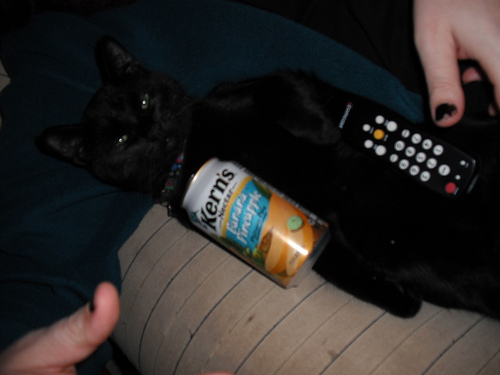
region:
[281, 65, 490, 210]
a cell phone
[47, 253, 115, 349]
a thumb with a black nail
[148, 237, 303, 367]
a striped pattern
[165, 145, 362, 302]
a can of something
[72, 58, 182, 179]
cats eyes in the dark area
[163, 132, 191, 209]
something of color under cat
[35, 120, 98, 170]
a cats ear in the darkness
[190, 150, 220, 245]
kerns is written on the can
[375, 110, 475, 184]
white buttons on cell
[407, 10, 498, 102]
a hand in the right corner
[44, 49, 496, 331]
black cat laying on his back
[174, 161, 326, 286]
can laying next to cat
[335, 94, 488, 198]
black remote control laying on cat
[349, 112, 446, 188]
white buttons on remote control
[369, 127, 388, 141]
yellow button on remote control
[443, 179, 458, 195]
red button on black remote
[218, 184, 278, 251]
white lettering on blue background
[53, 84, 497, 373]
cushion black cat is laying on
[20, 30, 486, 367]
hands of person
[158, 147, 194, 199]
collar on the black cat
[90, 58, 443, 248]
Cat laying on its back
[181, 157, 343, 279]
Can of fruit nectar next to a cat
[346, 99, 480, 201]
Remote control next too a cat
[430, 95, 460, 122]
Black painted finger nail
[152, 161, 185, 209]
Cat with collar on its neck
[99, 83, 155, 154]
Cat with green eyes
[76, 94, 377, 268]
Cat on a pillow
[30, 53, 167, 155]
Cat with perked ears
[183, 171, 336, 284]
Can of pineapple necter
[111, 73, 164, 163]
Cat with its eyes open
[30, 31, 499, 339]
Cat is laying down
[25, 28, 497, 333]
Black cat is laying down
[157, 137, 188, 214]
Cat is wearing a collar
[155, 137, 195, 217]
Black cat is wearing a collar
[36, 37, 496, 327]
Cat on its back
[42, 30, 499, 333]
Black cat on its back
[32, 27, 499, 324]
Cat laying on its back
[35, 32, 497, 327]
Black cat laying on its back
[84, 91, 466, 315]
Person wearing nail polish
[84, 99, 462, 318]
Person wearing black nail polish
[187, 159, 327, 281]
an aluminum can of fruit drink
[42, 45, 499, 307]
a black cat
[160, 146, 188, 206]
the collar on the cat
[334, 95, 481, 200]
cordless phone on the cat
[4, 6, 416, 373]
blue fabric under the cat's head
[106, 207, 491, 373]
beige fabric with blue stripes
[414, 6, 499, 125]
the hand on the top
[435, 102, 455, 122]
chipped nail polish on a hand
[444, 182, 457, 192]
red button on the phone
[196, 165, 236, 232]
the brand Kern's on the can